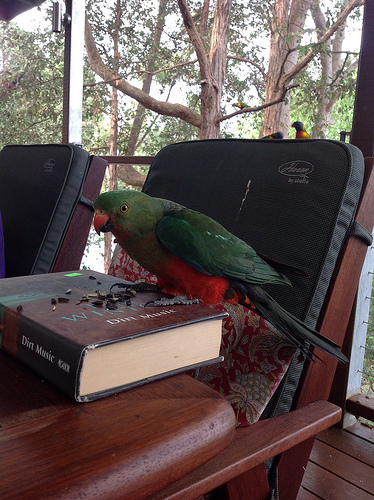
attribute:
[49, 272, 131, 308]
seed — for bird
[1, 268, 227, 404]
book — large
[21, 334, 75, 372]
writing — white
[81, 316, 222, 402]
pages — white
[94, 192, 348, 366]
bird — large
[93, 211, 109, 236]
beak — orange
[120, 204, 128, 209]
eye — black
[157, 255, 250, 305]
bottom — orange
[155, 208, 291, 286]
wing — green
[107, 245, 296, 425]
cushion — patterned, for chair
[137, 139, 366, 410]
cushion — dark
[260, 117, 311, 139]
birds — wild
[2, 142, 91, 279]
cushion — dark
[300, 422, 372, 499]
floor — wooden, brown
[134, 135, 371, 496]
chair — brown, wooden, wood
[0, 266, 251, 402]
book — thick, side, Dirt Music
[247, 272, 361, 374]
feathers — black, tail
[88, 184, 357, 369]
bird — green, red, black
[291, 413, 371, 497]
floor — brown, wood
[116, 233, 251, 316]
underneath — orange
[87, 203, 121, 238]
beak — red, black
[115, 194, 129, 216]
eye — black, yellow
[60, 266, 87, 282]
sticker — green